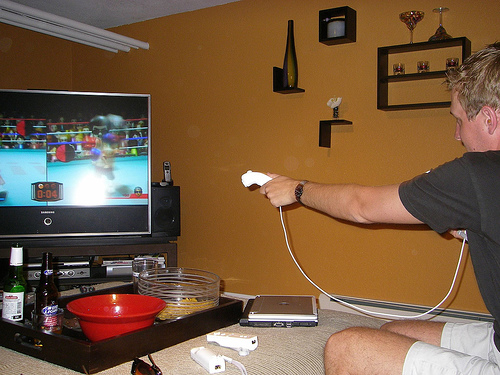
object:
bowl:
[138, 267, 221, 321]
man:
[258, 42, 500, 375]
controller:
[241, 169, 273, 188]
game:
[0, 89, 151, 238]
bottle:
[34, 252, 59, 329]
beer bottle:
[1, 242, 27, 324]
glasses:
[399, 11, 425, 45]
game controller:
[241, 170, 273, 188]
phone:
[163, 160, 172, 182]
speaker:
[151, 186, 182, 238]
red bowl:
[67, 294, 166, 343]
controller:
[191, 346, 248, 374]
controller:
[206, 331, 258, 356]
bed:
[0, 294, 387, 374]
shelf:
[376, 36, 471, 111]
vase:
[282, 20, 298, 88]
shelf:
[273, 66, 305, 94]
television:
[0, 88, 152, 238]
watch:
[295, 180, 309, 205]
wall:
[167, 23, 264, 108]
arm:
[295, 151, 498, 224]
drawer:
[0, 282, 244, 374]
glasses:
[428, 7, 453, 41]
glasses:
[446, 58, 459, 71]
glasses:
[416, 60, 430, 73]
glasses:
[393, 63, 406, 76]